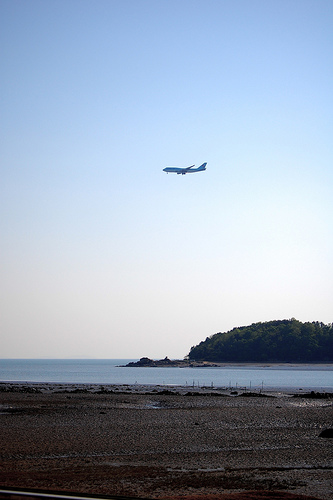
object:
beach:
[3, 405, 174, 494]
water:
[4, 355, 116, 389]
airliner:
[162, 162, 208, 175]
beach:
[235, 387, 323, 433]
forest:
[187, 317, 331, 364]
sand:
[10, 424, 68, 480]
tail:
[195, 161, 208, 172]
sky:
[0, 15, 66, 223]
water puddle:
[146, 400, 164, 408]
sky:
[187, 31, 275, 104]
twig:
[262, 381, 263, 389]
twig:
[250, 381, 252, 388]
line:
[3, 482, 84, 498]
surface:
[1, 481, 99, 498]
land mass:
[190, 360, 318, 365]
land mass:
[128, 391, 326, 481]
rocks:
[115, 357, 151, 367]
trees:
[253, 334, 259, 358]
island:
[116, 357, 215, 368]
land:
[114, 355, 221, 368]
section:
[0, 320, 332, 500]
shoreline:
[206, 357, 329, 369]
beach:
[128, 355, 319, 369]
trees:
[286, 320, 301, 360]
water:
[263, 365, 328, 387]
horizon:
[0, 357, 186, 363]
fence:
[162, 380, 263, 390]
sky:
[101, 294, 181, 359]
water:
[56, 356, 100, 380]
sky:
[157, 221, 325, 306]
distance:
[29, 309, 322, 364]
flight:
[162, 161, 208, 175]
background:
[90, 319, 332, 397]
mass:
[191, 317, 332, 365]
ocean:
[1, 357, 124, 387]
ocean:
[261, 363, 331, 382]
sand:
[1, 379, 86, 394]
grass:
[0, 387, 186, 403]